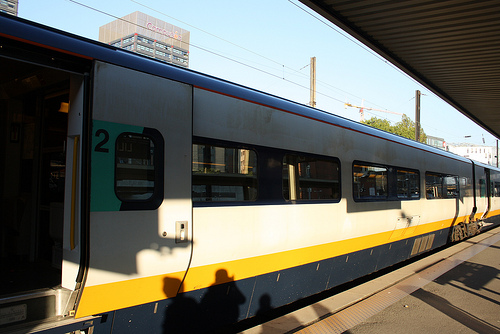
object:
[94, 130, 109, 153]
sign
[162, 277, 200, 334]
shadow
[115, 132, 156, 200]
window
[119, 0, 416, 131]
wires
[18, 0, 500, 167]
sky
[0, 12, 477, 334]
train car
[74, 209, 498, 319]
stripe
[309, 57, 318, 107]
pole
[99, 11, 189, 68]
building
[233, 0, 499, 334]
station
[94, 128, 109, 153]
number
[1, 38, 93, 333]
train door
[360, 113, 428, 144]
trees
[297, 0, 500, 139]
overhang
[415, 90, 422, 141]
pole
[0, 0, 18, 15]
building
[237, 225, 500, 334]
platform